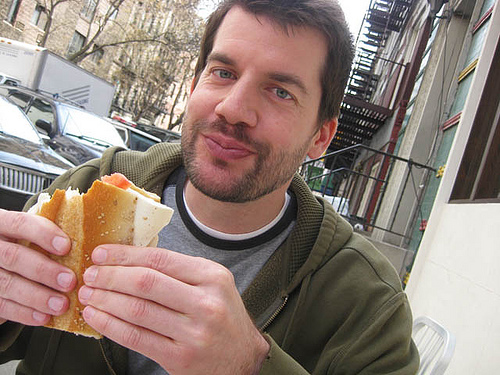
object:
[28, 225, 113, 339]
nails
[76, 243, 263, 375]
hands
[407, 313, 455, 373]
metal chair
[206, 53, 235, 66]
eye brows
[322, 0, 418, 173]
fire escape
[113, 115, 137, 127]
red car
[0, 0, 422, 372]
man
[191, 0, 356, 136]
hair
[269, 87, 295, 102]
eye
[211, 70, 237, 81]
eye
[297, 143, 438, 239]
handrails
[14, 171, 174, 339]
bread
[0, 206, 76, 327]
hand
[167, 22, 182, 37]
leaves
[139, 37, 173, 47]
branches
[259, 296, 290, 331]
zipper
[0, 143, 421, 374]
jacket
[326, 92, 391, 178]
platform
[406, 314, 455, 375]
chair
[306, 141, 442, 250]
railing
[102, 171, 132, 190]
meat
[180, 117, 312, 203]
goatee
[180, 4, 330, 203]
face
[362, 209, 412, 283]
sidewalk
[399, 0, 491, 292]
door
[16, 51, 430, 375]
man